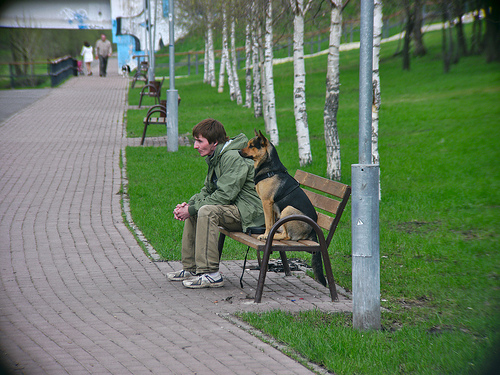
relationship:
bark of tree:
[372, 0, 377, 164] [179, 50, 212, 78]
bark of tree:
[325, 0, 349, 179] [324, 0, 339, 185]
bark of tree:
[312, 80, 342, 118] [250, 0, 263, 119]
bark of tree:
[297, 98, 309, 116] [3, 14, 54, 87]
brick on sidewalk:
[230, 353, 252, 363] [0, 50, 332, 373]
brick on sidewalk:
[274, 288, 297, 301] [2, 33, 408, 369]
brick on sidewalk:
[29, 249, 59, 274] [45, 200, 180, 346]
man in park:
[173, 100, 269, 302] [2, 1, 499, 368]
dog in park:
[228, 127, 318, 257] [2, 1, 499, 368]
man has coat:
[165, 113, 269, 289] [186, 133, 277, 232]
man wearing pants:
[165, 113, 269, 289] [176, 199, 271, 295]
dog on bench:
[237, 127, 328, 287] [213, 167, 346, 301]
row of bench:
[116, 55, 360, 277] [126, 58, 153, 96]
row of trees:
[195, 50, 385, 196] [394, 3, 499, 116]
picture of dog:
[6, 59, 492, 295] [236, 125, 329, 289]